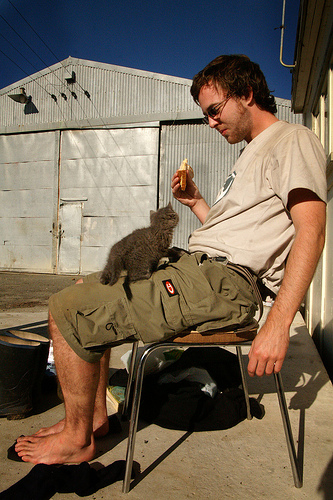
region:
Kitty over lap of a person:
[87, 192, 203, 295]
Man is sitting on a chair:
[8, 44, 327, 473]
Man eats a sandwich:
[76, 33, 331, 248]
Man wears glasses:
[135, 43, 331, 212]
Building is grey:
[0, 45, 199, 281]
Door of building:
[45, 187, 99, 283]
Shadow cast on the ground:
[285, 310, 330, 432]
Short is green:
[41, 242, 266, 358]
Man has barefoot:
[7, 37, 331, 480]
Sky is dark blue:
[11, 4, 305, 69]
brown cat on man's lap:
[98, 201, 181, 298]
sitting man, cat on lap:
[14, 64, 331, 468]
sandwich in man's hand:
[171, 157, 196, 189]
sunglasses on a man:
[200, 97, 237, 121]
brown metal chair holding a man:
[117, 320, 302, 493]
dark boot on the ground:
[1, 328, 50, 417]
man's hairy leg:
[15, 311, 110, 465]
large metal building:
[0, 57, 304, 272]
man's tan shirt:
[188, 119, 328, 291]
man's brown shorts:
[46, 251, 259, 362]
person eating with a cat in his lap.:
[33, 41, 317, 464]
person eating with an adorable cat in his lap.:
[42, 57, 314, 435]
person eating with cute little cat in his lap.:
[44, 49, 311, 418]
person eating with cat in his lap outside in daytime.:
[44, 55, 314, 405]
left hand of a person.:
[240, 312, 288, 378]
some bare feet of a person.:
[5, 408, 113, 475]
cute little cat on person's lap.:
[86, 200, 184, 319]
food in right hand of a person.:
[159, 156, 200, 202]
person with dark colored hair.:
[169, 52, 284, 139]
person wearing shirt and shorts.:
[37, 48, 306, 415]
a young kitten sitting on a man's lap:
[77, 194, 190, 309]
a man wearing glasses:
[185, 44, 270, 166]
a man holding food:
[161, 51, 265, 199]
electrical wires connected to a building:
[0, 62, 88, 109]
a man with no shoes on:
[0, 372, 127, 471]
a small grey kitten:
[100, 205, 185, 288]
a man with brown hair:
[183, 58, 285, 152]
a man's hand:
[241, 257, 313, 396]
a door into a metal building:
[47, 177, 89, 293]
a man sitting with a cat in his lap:
[112, 43, 299, 485]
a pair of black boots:
[1, 324, 59, 426]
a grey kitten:
[93, 201, 179, 285]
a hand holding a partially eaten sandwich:
[166, 154, 208, 206]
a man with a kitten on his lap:
[48, 49, 329, 407]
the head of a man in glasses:
[187, 45, 296, 150]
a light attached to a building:
[0, 52, 69, 124]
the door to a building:
[45, 181, 89, 275]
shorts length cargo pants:
[47, 249, 263, 357]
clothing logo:
[155, 273, 182, 297]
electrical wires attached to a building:
[30, 53, 111, 106]